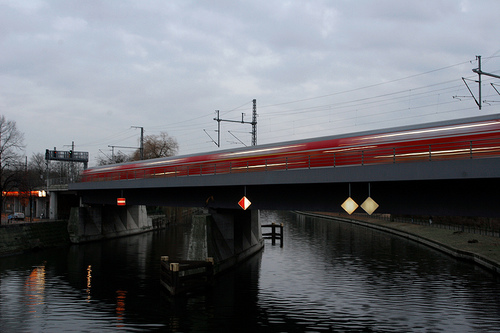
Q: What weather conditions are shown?
A: It is overcast.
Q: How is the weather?
A: It is overcast.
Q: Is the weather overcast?
A: Yes, it is overcast.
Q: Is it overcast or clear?
A: It is overcast.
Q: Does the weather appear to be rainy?
A: No, it is overcast.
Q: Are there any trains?
A: Yes, there is a train.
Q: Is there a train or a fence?
A: Yes, there is a train.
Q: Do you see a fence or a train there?
A: Yes, there is a train.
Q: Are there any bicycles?
A: No, there are no bicycles.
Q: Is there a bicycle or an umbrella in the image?
A: No, there are no bicycles or umbrellas.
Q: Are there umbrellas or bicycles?
A: No, there are no bicycles or umbrellas.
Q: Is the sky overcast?
A: Yes, the sky is overcast.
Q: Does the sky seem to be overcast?
A: Yes, the sky is overcast.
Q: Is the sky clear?
A: No, the sky is overcast.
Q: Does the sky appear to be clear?
A: No, the sky is overcast.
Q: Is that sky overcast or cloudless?
A: The sky is overcast.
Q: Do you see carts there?
A: No, there are no carts.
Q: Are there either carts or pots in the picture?
A: No, there are no carts or pots.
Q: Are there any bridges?
A: Yes, there is a bridge.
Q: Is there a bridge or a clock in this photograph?
A: Yes, there is a bridge.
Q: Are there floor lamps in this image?
A: No, there are no floor lamps.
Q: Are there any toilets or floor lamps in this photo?
A: No, there are no floor lamps or toilets.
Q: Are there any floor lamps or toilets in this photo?
A: No, there are no floor lamps or toilets.